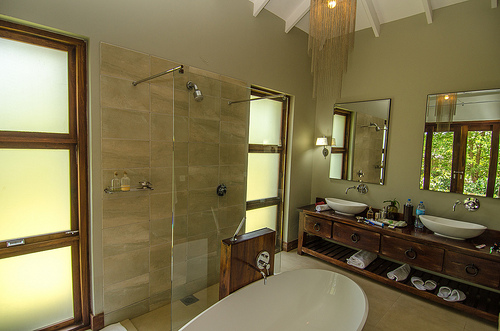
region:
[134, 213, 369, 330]
a white bathroom tub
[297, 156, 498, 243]
two bathroom sinks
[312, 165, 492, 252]
two white bathroom sinks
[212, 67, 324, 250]
a window in the bathroom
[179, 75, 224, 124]
a shower head on the wall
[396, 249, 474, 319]
white slippers under the sink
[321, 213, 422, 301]
two white towels under the sink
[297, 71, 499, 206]
two mirrors on the wall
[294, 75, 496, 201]
a wall with two windows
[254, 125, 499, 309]
two sinks on a brown table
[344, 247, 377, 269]
WHITE FOLDED TOWEL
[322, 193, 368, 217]
WHITE ABOVE COUNTER SINK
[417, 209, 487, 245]
WHITE ABOVE COUNTER SINK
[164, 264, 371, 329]
WHITE PORCELAIN BATH TUB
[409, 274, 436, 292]
A PAIR OF WHITE SLIPPERS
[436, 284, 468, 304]
A PAIR OF WHITE SLIPPERS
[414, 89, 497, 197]
MIRROR REFLECTING THE OUTSIDE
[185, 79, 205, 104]
SILVER SHOWER HEAD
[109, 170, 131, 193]
BOTTLES OF SHAMPOO AND CONDITIONER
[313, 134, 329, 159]
WALL SCONCE WITH A WHITE SHADE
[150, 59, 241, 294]
glass wall on shower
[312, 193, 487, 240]
two bowl shaped sinks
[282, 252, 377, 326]
edge of white tub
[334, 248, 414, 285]
rolled up white towels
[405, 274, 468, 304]
two pair of white slippers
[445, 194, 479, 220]
metal faucet in wall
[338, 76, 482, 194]
two mirrors on wall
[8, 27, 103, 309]
three panels of windows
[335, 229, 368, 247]
handle on wood drawer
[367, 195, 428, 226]
toiletries on top of vanity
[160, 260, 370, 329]
Bathtub is white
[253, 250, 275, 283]
Faucet on wooden piece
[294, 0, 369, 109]
Contemporary light above white bath tub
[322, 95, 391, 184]
Large square mirror above faucet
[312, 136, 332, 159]
Small lamp next to mirror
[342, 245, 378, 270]
White towel under counter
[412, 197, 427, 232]
Plastic bottle next to white sink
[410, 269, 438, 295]
White slippers next to white towel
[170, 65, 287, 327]
Glass shower wall separating bath tub and shower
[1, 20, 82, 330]
Large wooden window next to shower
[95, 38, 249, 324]
shower as stone wall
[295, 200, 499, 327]
large wooden sink with shelf underneath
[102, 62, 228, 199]
metal fixtures inside shower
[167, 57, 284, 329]
glass shower wall beside tub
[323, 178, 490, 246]
two sink basins under sink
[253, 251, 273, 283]
bath tub faucet is metal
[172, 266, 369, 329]
white bath tub on floor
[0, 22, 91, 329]
wooden trim on glass window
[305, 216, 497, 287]
four drawers under sink basin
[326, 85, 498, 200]
two mirrors above sink basins